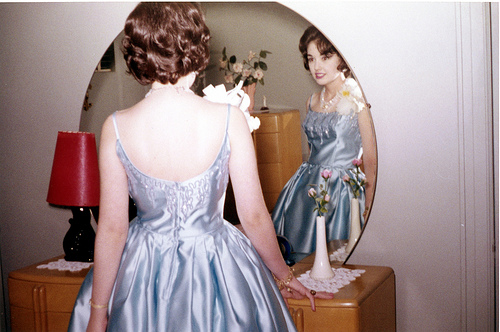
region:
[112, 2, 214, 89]
the head of a woman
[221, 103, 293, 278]
the arm of a woman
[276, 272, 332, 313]
the hand of a woman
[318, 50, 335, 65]
the eye of a woman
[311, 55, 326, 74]
the nose of a woman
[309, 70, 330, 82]
the mouth of a woman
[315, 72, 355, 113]
a necklace on the woman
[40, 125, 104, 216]
a red lamp shade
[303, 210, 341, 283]
a white vase on the dresser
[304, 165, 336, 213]
pink flowers in the vase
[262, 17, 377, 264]
Woman's image in a mirror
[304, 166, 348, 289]
White vase with flowers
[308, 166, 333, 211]
Two pink flowers in vase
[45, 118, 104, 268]
Lamp with red lamp shade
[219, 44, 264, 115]
Flowers in vase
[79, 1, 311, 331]
Woman formally dressed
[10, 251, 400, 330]
Dresser in front of woman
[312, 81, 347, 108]
Diamond necklace around woman's neck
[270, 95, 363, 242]
Woman has on cinderella-style dress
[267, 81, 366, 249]
Dress is old fashioned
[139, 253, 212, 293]
the dress is very elegant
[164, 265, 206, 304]
the dress is a blue color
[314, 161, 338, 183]
the flower is pink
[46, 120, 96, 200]
the lamp shade is red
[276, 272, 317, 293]
the bracelet in on her right arm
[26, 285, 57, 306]
the dresser is brown in color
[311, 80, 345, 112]
the necklace is very elegant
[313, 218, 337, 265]
the vase is white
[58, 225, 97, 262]
the lamp base is black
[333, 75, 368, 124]
the ca sage is white and yellow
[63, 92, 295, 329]
a long silver dress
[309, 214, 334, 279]
a tall light pink vase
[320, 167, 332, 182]
a pink rose bud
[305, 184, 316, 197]
a pink rose bud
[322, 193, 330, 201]
a pink rose bud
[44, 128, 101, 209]
a dark red shade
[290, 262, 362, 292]
a light pink doily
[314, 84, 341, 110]
a necklace strand of pearls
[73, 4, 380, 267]
a large vanity mirror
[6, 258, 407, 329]
a brown dresser drawers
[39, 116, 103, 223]
red lamp shade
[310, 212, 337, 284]
white vase on dresser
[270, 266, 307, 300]
gold bracelet on woman's wrist on the right hand side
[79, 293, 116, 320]
gold ribbon on woman's left wrist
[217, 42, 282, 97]
flowers in the mirror at the top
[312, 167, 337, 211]
pink flowers (NOT in the mirror)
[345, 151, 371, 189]
pink flowers reflection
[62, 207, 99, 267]
black base of the lamp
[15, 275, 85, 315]
left hand side top drawer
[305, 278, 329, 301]
ring on woman's right hand